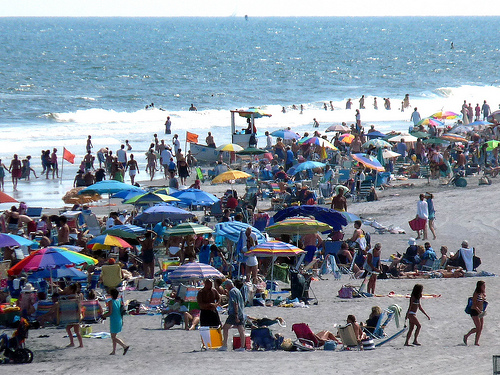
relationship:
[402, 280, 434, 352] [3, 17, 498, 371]
woman walking on beach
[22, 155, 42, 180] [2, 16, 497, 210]
girl kicking water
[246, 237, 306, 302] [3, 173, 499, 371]
beach umbrella in sand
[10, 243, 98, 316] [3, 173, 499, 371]
beach umbrella in sand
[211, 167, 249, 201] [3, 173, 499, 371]
beach umbrella in sand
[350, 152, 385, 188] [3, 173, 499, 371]
beach umbrella in sand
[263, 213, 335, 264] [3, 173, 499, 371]
beach umbrella in sand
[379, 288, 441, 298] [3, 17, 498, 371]
towel on beach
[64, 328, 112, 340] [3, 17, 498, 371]
towel on beach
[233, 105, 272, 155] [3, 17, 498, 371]
lifeguard tower on beach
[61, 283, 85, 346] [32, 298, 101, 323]
person holding beach chair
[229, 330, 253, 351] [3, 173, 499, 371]
cooler on sand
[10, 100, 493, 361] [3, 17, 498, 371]
people on beach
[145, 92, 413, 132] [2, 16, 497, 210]
people in water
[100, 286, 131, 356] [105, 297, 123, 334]
woman wearing dress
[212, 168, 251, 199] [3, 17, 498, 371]
umbrella on beach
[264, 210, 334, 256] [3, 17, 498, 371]
umbrella on beach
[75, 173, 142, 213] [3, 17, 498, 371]
umbrella on beach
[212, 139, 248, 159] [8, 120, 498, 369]
umbrella in beach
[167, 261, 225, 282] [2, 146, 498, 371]
umbrella in beach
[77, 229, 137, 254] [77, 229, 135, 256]
umbrella in beach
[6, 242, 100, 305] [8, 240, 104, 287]
umbrella in beach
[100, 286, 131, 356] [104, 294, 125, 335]
woman wears dress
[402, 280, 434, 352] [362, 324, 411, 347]
woman holds beach chair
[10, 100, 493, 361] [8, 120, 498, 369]
people on beach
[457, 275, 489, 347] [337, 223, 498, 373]
girl on beach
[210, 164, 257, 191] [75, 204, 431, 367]
people on beach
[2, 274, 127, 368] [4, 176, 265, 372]
people on beach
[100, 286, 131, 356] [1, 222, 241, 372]
woman on beach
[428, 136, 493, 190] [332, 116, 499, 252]
people on beach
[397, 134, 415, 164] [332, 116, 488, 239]
people on beach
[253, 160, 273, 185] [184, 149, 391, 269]
people on beach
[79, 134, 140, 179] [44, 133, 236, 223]
people on beach